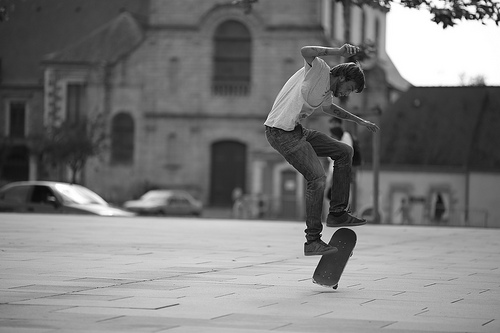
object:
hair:
[330, 62, 365, 94]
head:
[330, 62, 365, 97]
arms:
[300, 46, 339, 69]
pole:
[372, 115, 379, 224]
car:
[122, 189, 203, 216]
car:
[0, 180, 138, 217]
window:
[211, 19, 254, 98]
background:
[0, 0, 499, 273]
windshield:
[56, 183, 108, 205]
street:
[0, 212, 499, 331]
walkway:
[0, 212, 498, 332]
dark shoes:
[304, 240, 338, 256]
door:
[273, 163, 306, 221]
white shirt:
[263, 56, 333, 131]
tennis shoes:
[326, 211, 368, 228]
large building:
[0, 0, 499, 230]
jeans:
[264, 123, 353, 241]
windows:
[0, 3, 462, 223]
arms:
[321, 93, 359, 122]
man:
[263, 43, 381, 256]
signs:
[386, 181, 454, 224]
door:
[208, 138, 248, 211]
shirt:
[263, 56, 333, 132]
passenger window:
[29, 185, 57, 205]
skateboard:
[312, 228, 357, 288]